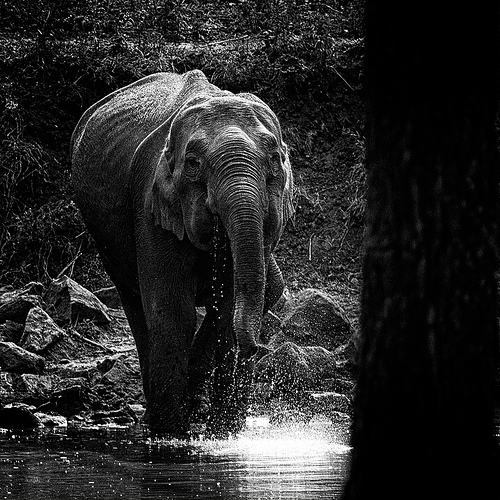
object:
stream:
[103, 218, 354, 457]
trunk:
[209, 121, 272, 365]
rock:
[16, 304, 75, 354]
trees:
[0, 0, 398, 287]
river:
[0, 414, 358, 498]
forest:
[0, 0, 498, 498]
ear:
[140, 145, 188, 243]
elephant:
[67, 67, 299, 443]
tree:
[339, 0, 499, 498]